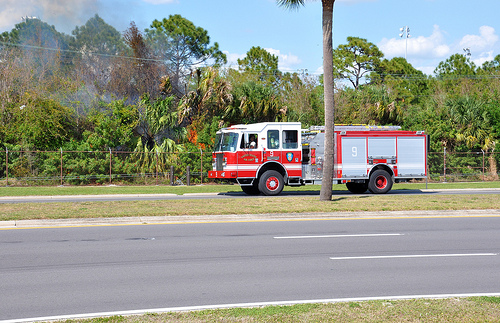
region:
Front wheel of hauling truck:
[259, 167, 285, 194]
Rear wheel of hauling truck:
[369, 167, 395, 195]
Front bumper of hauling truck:
[203, 168, 239, 180]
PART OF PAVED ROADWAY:
[48, 247, 173, 273]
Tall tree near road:
[318, 6, 338, 204]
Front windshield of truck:
[210, 131, 242, 148]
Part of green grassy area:
[33, 198, 88, 218]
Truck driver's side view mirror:
[242, 132, 249, 149]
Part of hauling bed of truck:
[338, 122, 434, 183]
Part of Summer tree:
[383, 72, 429, 117]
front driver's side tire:
[258, 169, 286, 193]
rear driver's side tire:
[368, 165, 390, 193]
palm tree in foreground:
[314, 0, 339, 202]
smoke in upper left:
[0, 3, 177, 100]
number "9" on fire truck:
[345, 143, 363, 160]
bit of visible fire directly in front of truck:
[181, 121, 213, 150]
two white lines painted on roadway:
[260, 228, 499, 266]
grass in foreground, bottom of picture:
[49, 294, 499, 321]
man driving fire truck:
[244, 133, 260, 153]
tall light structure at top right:
[393, 16, 418, 66]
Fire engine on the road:
[168, 99, 427, 184]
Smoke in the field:
[56, 28, 180, 162]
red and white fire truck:
[223, 112, 497, 231]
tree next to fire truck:
[304, 53, 355, 230]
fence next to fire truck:
[35, 135, 212, 192]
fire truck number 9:
[239, 126, 312, 195]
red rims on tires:
[261, 168, 288, 208]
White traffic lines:
[214, 218, 484, 300]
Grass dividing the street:
[59, 186, 381, 220]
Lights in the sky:
[373, 16, 428, 83]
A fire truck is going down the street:
[30, 25, 465, 286]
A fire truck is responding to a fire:
[10, 7, 467, 308]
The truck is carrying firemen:
[5, 40, 495, 297]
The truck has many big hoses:
[15, 37, 497, 287]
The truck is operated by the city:
[21, 30, 476, 300]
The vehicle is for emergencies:
[21, 45, 487, 295]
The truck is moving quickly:
[13, 20, 473, 292]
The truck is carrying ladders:
[18, 30, 465, 291]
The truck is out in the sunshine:
[17, 21, 462, 296]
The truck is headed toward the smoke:
[9, 20, 477, 290]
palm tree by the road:
[282, 2, 336, 199]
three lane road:
[2, 214, 494, 304]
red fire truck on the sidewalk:
[213, 121, 426, 190]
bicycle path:
[0, 188, 498, 205]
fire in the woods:
[167, 103, 207, 151]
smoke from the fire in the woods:
[1, 0, 182, 139]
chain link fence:
[2, 149, 499, 176]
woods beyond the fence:
[0, 25, 495, 177]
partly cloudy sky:
[174, 2, 496, 68]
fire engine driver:
[245, 136, 257, 147]